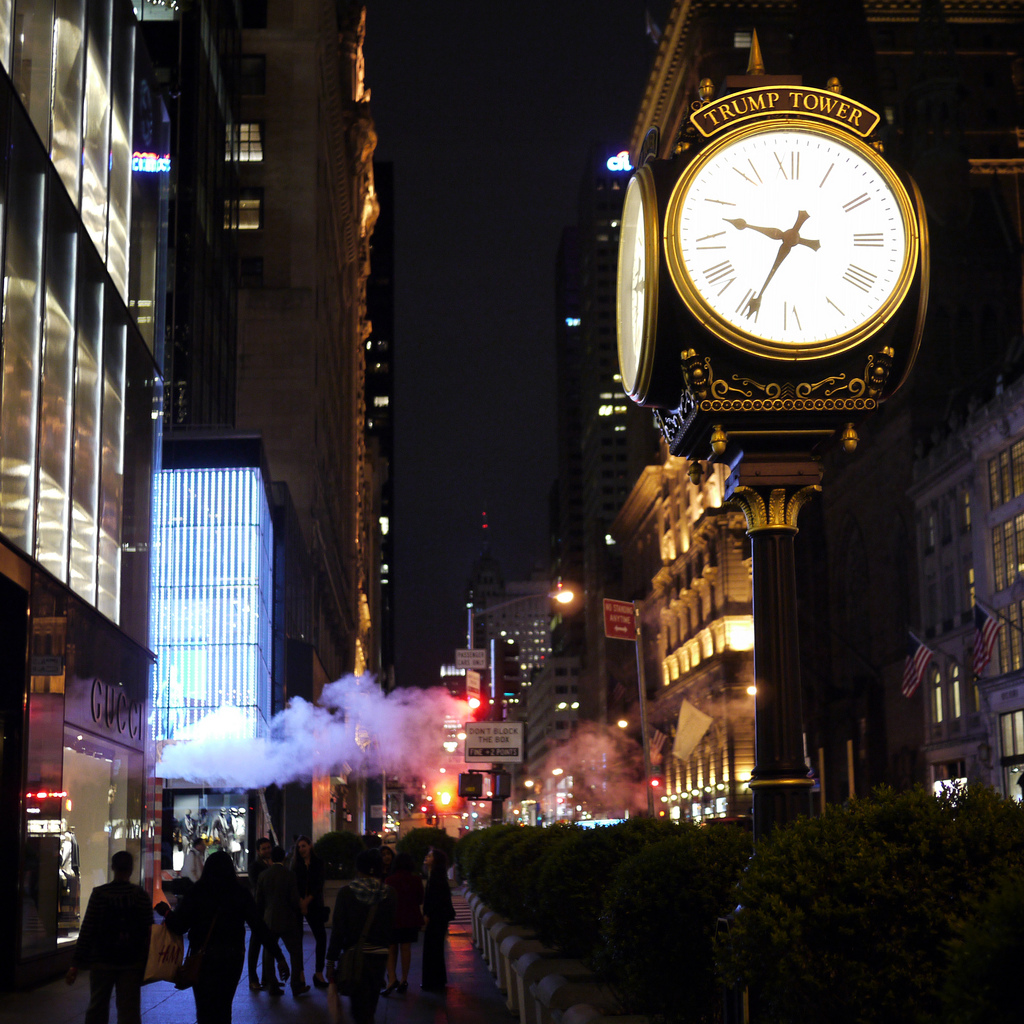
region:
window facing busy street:
[998, 446, 1018, 513]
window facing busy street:
[928, 668, 948, 724]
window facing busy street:
[952, 659, 964, 728]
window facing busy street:
[961, 487, 975, 530]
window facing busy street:
[924, 509, 938, 556]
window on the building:
[712, 619, 758, 651]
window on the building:
[694, 635, 718, 656]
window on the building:
[661, 653, 674, 685]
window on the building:
[665, 644, 686, 683]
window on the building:
[722, 726, 745, 780]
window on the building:
[946, 669, 984, 731]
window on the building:
[921, 664, 951, 732]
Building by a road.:
[601, 396, 808, 818]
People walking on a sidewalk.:
[87, 786, 458, 1018]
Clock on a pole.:
[571, 85, 927, 455]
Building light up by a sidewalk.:
[151, 434, 313, 814]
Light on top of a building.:
[477, 493, 501, 560]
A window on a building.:
[947, 658, 968, 722]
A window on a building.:
[955, 551, 982, 600]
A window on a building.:
[944, 564, 964, 619]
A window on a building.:
[923, 573, 953, 624]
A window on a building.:
[704, 552, 723, 584]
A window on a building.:
[661, 728, 678, 758]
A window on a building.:
[701, 741, 722, 773]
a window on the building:
[86, 292, 222, 548]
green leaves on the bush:
[883, 811, 934, 878]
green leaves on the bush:
[993, 888, 1022, 964]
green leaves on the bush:
[690, 859, 733, 929]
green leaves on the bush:
[595, 818, 622, 883]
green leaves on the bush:
[646, 859, 711, 957]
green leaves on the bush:
[484, 812, 568, 899]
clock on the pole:
[669, 101, 932, 378]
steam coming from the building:
[132, 655, 483, 808]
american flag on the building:
[955, 590, 1006, 689]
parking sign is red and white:
[587, 591, 648, 656]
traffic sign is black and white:
[455, 715, 528, 776]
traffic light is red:
[462, 688, 485, 718]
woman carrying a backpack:
[360, 862, 427, 952]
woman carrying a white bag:
[133, 913, 195, 993]